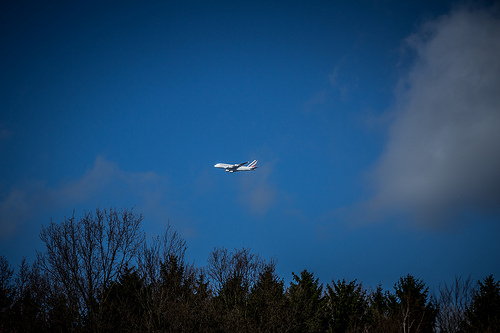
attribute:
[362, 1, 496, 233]
cloud — white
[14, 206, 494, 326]
trees — green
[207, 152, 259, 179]
plane — white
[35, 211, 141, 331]
tree — bare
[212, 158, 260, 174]
plane — airborne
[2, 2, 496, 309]
sky — clear, blue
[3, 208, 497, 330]
plants — green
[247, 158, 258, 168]
logo — red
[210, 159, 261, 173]
jet — white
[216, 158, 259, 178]
jet — airborne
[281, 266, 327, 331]
leaves — green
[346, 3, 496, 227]
cloud — large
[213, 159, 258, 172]
airplane — large, white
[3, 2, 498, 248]
clouds — grey